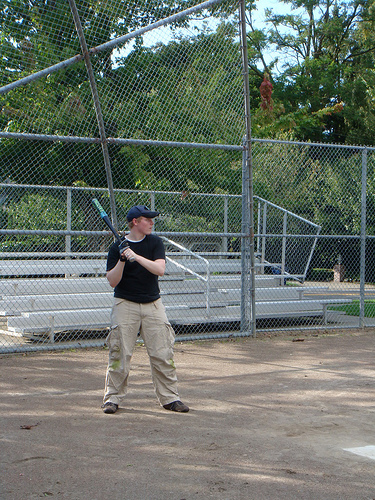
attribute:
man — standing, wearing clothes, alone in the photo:
[102, 205, 192, 416]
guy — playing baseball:
[101, 205, 194, 417]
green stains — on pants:
[107, 345, 123, 374]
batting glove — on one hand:
[117, 237, 129, 260]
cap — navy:
[118, 208, 169, 226]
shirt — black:
[110, 235, 180, 286]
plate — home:
[342, 430, 372, 451]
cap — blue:
[121, 208, 200, 235]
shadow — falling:
[67, 404, 298, 471]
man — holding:
[81, 202, 213, 382]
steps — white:
[20, 270, 105, 328]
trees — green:
[167, 53, 332, 182]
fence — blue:
[209, 119, 366, 232]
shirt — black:
[114, 241, 199, 271]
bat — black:
[75, 182, 124, 231]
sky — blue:
[242, 14, 340, 104]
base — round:
[120, 237, 158, 280]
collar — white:
[116, 235, 148, 253]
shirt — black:
[104, 231, 189, 290]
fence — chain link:
[215, 137, 354, 272]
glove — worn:
[116, 236, 125, 250]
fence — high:
[121, 21, 263, 163]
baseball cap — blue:
[129, 205, 152, 217]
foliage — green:
[263, 97, 349, 204]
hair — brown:
[124, 220, 132, 227]